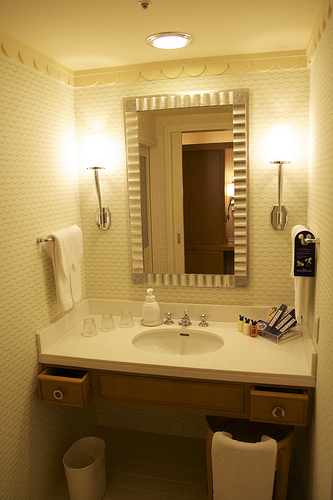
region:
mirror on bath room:
[131, 90, 259, 295]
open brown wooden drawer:
[27, 366, 87, 410]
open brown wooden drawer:
[255, 388, 319, 444]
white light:
[243, 125, 291, 155]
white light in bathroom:
[65, 135, 120, 175]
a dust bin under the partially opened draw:
[35, 353, 109, 498]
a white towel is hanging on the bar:
[34, 223, 83, 315]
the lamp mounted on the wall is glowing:
[81, 131, 113, 230]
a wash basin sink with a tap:
[131, 298, 223, 359]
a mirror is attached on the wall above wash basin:
[121, 89, 251, 366]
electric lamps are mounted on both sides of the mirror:
[79, 88, 294, 286]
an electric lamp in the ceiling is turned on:
[50, 0, 302, 71]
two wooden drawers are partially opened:
[33, 359, 316, 430]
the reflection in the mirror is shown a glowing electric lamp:
[125, 97, 248, 287]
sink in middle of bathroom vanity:
[37, 297, 317, 386]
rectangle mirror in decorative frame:
[122, 89, 248, 288]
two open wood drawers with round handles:
[35, 363, 313, 428]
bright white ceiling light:
[152, 30, 192, 52]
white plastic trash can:
[60, 436, 108, 497]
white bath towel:
[210, 422, 275, 498]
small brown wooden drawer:
[35, 362, 91, 406]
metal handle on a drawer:
[271, 408, 285, 417]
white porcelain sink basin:
[127, 326, 220, 358]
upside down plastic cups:
[80, 317, 134, 336]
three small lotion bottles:
[235, 313, 260, 337]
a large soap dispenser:
[143, 288, 161, 326]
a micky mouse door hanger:
[294, 227, 316, 275]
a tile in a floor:
[106, 435, 120, 447]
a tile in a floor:
[128, 434, 145, 445]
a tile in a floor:
[146, 437, 163, 448]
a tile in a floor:
[167, 436, 183, 451]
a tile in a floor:
[186, 442, 204, 456]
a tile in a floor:
[187, 450, 201, 466]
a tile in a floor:
[169, 453, 189, 470]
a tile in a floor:
[148, 447, 166, 462]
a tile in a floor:
[131, 445, 145, 462]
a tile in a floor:
[111, 443, 132, 462]